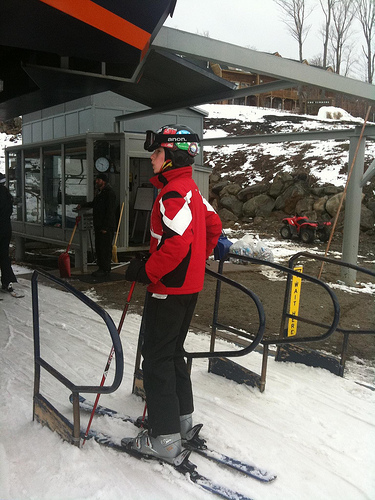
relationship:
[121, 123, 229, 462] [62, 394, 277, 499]
man wearing skis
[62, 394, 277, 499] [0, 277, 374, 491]
skis in snow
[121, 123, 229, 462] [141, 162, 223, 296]
man wearing jacket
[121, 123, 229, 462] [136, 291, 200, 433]
man wearing pants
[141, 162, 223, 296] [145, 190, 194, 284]
jacket has patches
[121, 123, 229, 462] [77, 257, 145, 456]
man holding ski pole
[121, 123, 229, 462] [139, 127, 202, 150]
man has goggles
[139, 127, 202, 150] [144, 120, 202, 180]
goggles around head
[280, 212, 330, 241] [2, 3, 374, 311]
atv in background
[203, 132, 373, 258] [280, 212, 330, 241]
hill next to atv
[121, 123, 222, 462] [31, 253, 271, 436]
man at entrance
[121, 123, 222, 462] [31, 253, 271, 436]
man waiting at entrance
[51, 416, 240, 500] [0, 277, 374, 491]
ski in snow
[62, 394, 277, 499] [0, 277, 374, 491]
ski in snow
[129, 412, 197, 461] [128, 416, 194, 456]
ski boots on feet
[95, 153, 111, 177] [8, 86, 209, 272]
clock in building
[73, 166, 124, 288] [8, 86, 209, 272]
man front of building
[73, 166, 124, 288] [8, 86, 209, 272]
man standing front of building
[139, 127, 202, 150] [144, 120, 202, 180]
goggles on head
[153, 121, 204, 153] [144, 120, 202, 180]
helmet on head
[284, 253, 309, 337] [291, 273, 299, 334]
sign saying wait here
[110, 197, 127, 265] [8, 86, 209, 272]
broom resting against building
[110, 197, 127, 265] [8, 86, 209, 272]
broom against building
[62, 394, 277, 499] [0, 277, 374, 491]
skis on snow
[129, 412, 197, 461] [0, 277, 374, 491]
ski boots on snow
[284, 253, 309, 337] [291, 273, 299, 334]
sign says wait here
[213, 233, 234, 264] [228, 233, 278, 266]
trashcan with trash bags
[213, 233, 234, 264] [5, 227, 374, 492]
trashcan on ground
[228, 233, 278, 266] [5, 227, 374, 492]
trash bags on ground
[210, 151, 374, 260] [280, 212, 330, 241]
rocks next to atv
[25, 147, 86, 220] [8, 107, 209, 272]
windows on building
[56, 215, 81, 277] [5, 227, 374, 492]
shovel on ground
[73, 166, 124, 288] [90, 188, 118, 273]
man wearing black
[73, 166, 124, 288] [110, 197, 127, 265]
man next to broom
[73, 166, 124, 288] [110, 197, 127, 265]
man standing next to broom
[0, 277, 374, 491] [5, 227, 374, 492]
snow on ground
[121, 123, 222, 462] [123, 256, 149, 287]
man wearing gloves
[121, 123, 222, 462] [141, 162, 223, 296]
man wearing jacket